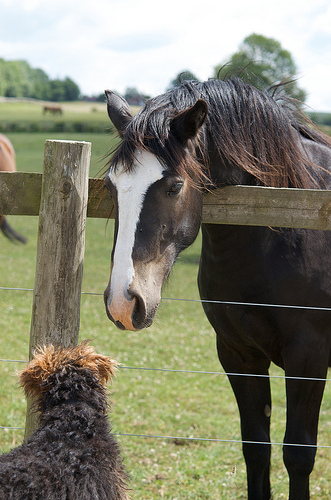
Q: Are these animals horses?
A: No, there are both horses and dogs.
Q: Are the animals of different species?
A: Yes, they are horses and dogs.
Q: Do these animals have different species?
A: Yes, they are horses and dogs.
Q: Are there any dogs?
A: Yes, there is a dog.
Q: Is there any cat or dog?
A: Yes, there is a dog.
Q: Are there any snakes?
A: No, there are no snakes.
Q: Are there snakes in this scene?
A: No, there are no snakes.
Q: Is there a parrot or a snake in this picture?
A: No, there are no snakes or parrots.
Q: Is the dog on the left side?
A: Yes, the dog is on the left of the image.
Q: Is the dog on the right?
A: No, the dog is on the left of the image.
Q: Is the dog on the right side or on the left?
A: The dog is on the left of the image.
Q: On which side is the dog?
A: The dog is on the left of the image.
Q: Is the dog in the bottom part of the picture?
A: Yes, the dog is in the bottom of the image.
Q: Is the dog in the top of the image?
A: No, the dog is in the bottom of the image.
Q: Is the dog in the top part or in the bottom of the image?
A: The dog is in the bottom of the image.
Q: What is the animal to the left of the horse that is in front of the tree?
A: The animal is a dog.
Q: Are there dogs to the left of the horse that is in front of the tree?
A: Yes, there is a dog to the left of the horse.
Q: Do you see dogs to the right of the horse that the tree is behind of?
A: No, the dog is to the left of the horse.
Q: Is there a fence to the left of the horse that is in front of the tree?
A: No, there is a dog to the left of the horse.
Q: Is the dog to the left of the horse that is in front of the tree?
A: Yes, the dog is to the left of the horse.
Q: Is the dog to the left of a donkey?
A: No, the dog is to the left of the horse.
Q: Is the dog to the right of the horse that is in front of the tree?
A: No, the dog is to the left of the horse.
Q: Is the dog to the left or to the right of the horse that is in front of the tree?
A: The dog is to the left of the horse.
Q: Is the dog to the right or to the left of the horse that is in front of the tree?
A: The dog is to the left of the horse.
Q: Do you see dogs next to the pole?
A: Yes, there is a dog next to the pole.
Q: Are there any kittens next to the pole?
A: No, there is a dog next to the pole.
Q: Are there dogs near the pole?
A: Yes, there is a dog near the pole.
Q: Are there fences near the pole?
A: No, there is a dog near the pole.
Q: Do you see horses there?
A: Yes, there is a horse.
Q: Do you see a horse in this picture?
A: Yes, there is a horse.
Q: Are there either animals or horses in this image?
A: Yes, there is a horse.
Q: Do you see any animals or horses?
A: Yes, there is a horse.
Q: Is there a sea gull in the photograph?
A: No, there are no seagulls.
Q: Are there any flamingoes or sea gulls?
A: No, there are no sea gulls or flamingoes.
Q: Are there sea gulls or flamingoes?
A: No, there are no sea gulls or flamingoes.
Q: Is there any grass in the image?
A: Yes, there is grass.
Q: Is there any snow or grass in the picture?
A: Yes, there is grass.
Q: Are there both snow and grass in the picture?
A: No, there is grass but no snow.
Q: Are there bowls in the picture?
A: No, there are no bowls.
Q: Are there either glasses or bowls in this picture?
A: No, there are no bowls or glasses.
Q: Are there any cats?
A: No, there are no cats.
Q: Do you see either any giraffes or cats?
A: No, there are no cats or giraffes.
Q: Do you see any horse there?
A: Yes, there is a horse.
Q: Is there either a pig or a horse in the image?
A: Yes, there is a horse.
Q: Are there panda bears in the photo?
A: No, there are no panda bears.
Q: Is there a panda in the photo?
A: No, there are no pandas.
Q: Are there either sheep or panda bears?
A: No, there are no panda bears or sheep.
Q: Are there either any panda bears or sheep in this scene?
A: No, there are no panda bears or sheep.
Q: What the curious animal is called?
A: The animal is a horse.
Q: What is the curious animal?
A: The animal is a horse.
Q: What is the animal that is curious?
A: The animal is a horse.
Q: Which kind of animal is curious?
A: The animal is a horse.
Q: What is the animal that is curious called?
A: The animal is a horse.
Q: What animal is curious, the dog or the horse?
A: The horse is curious.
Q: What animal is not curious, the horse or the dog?
A: The dog is not curious.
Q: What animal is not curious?
A: The animal is a dog.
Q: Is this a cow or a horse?
A: This is a horse.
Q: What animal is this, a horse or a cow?
A: This is a horse.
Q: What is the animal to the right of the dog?
A: The animal is a horse.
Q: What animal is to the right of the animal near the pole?
A: The animal is a horse.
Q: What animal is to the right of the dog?
A: The animal is a horse.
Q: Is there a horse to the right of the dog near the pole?
A: Yes, there is a horse to the right of the dog.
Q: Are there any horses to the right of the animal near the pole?
A: Yes, there is a horse to the right of the dog.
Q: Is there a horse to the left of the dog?
A: No, the horse is to the right of the dog.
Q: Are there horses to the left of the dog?
A: No, the horse is to the right of the dog.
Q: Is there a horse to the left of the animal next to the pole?
A: No, the horse is to the right of the dog.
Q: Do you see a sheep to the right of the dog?
A: No, there is a horse to the right of the dog.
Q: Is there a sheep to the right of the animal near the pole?
A: No, there is a horse to the right of the dog.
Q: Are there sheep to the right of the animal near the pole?
A: No, there is a horse to the right of the dog.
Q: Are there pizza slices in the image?
A: No, there are no pizza slices.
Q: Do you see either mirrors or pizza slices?
A: No, there are no pizza slices or mirrors.